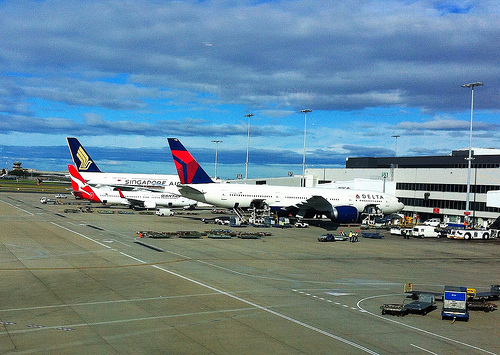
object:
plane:
[167, 137, 405, 223]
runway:
[0, 190, 499, 354]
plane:
[67, 164, 212, 209]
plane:
[66, 135, 225, 194]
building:
[229, 148, 499, 229]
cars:
[448, 228, 498, 240]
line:
[2, 305, 259, 336]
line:
[1, 291, 221, 312]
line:
[1, 199, 379, 354]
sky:
[0, 2, 498, 151]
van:
[412, 225, 440, 238]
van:
[422, 215, 439, 226]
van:
[156, 207, 174, 215]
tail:
[166, 136, 213, 183]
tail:
[68, 165, 101, 201]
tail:
[65, 137, 100, 171]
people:
[347, 230, 360, 242]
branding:
[360, 191, 385, 199]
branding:
[159, 194, 182, 199]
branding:
[124, 179, 181, 188]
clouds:
[0, 109, 305, 138]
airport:
[0, 82, 499, 354]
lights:
[242, 113, 256, 120]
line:
[211, 80, 482, 213]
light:
[461, 81, 482, 89]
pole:
[465, 85, 476, 210]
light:
[299, 109, 307, 113]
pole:
[301, 115, 309, 174]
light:
[244, 111, 252, 116]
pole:
[245, 117, 251, 180]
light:
[211, 139, 223, 144]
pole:
[215, 145, 219, 178]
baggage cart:
[440, 283, 471, 321]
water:
[0, 161, 346, 177]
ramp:
[234, 209, 248, 226]